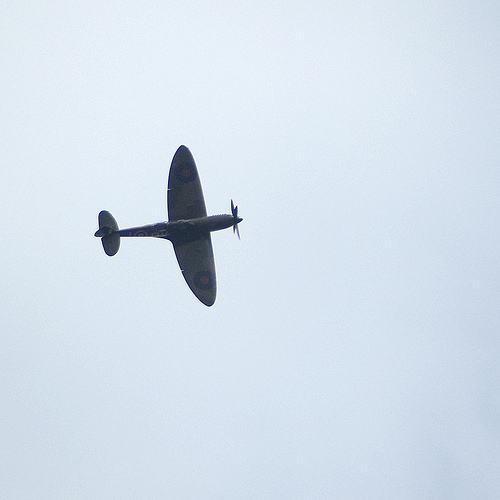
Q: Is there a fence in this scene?
A: No, there are no fences.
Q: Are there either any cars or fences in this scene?
A: No, there are no fences or cars.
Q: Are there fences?
A: No, there are no fences.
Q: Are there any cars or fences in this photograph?
A: No, there are no fences or cars.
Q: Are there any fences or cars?
A: No, there are no fences or cars.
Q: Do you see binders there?
A: No, there are no binders.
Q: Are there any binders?
A: No, there are no binders.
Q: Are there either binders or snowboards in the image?
A: No, there are no binders or snowboards.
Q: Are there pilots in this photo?
A: No, there are no pilots.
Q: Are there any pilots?
A: No, there are no pilots.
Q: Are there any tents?
A: No, there are no tents.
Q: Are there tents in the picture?
A: No, there are no tents.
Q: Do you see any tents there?
A: No, there are no tents.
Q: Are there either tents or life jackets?
A: No, there are no tents or life jackets.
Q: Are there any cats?
A: No, there are no cats.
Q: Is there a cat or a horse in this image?
A: No, there are no cats or horses.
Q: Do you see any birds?
A: No, there are no birds.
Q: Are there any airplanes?
A: Yes, there is an airplane.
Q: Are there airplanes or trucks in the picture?
A: Yes, there is an airplane.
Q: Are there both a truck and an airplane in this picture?
A: No, there is an airplane but no trucks.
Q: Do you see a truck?
A: No, there are no trucks.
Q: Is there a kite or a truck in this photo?
A: No, there are no trucks or kites.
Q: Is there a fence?
A: No, there are no fences.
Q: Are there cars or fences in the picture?
A: No, there are no fences or cars.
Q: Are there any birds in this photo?
A: No, there are no birds.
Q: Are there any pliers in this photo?
A: No, there are no pliers.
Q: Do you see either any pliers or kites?
A: No, there are no pliers or kites.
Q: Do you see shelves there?
A: No, there are no shelves.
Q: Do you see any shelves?
A: No, there are no shelves.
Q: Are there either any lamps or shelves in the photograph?
A: No, there are no shelves or lamps.